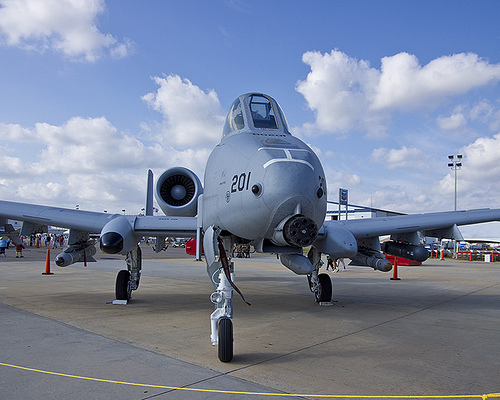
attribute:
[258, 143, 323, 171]
lines — white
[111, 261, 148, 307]
wheel — left wheel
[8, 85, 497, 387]
warthog — gray, a10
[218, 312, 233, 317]
handle — part 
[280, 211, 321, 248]
gun — large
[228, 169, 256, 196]
201" —  number 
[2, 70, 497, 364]
jet — side 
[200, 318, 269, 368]
tire — black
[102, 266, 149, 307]
tire — black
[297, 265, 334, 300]
tire — black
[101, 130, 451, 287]
jet — grey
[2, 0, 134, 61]
cloud — white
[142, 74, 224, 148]
cloud — white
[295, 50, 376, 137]
cloud — white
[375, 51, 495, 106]
cloud — white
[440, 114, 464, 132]
cloud — white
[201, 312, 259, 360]
tire — black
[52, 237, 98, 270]
missle — under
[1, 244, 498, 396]
floor — part 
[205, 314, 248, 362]
tire — black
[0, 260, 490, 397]
floor — part 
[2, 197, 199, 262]
wing — left wing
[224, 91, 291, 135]
cockpit — glass 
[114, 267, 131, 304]
tire — black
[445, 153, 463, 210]
pole — light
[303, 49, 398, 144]
cloud — part 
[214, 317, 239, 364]
tire — black 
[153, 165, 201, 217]
engine — large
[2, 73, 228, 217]
clouds — white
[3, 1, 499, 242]
sky — blue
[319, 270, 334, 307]
plane wheel — right wheel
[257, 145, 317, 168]
lines — white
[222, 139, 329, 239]
nose — nose of plane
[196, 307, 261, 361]
wheel — front wheel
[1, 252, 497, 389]
floor — part 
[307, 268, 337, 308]
tire — black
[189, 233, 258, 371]
gear — landing gear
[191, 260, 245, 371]
gear — landing gear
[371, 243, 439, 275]
missle — under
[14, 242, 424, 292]
cones — orange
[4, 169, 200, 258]
wing — right wing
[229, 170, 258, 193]
201 — airplane number 